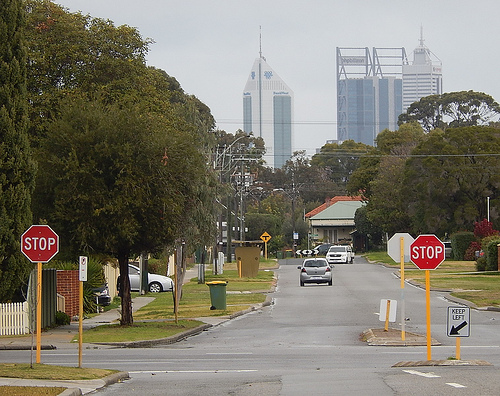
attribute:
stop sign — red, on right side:
[405, 232, 445, 275]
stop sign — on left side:
[15, 224, 61, 367]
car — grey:
[302, 262, 334, 284]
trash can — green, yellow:
[212, 279, 227, 313]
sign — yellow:
[261, 236, 276, 267]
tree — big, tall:
[47, 81, 206, 314]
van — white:
[325, 241, 351, 262]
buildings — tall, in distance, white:
[241, 21, 443, 168]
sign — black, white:
[448, 307, 469, 337]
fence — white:
[1, 302, 40, 335]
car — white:
[112, 256, 181, 298]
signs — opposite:
[378, 236, 415, 333]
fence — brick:
[42, 275, 94, 325]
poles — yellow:
[390, 251, 435, 357]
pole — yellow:
[422, 268, 431, 360]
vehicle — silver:
[294, 262, 339, 295]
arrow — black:
[449, 322, 464, 336]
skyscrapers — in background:
[238, 23, 440, 155]